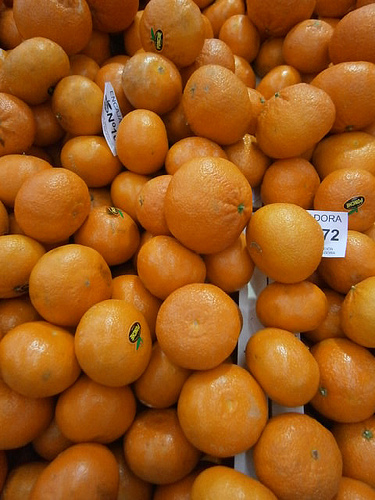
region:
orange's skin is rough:
[166, 165, 243, 248]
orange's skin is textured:
[174, 148, 212, 223]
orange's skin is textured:
[173, 168, 230, 232]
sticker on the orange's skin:
[124, 318, 149, 351]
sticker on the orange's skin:
[112, 316, 145, 345]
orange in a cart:
[140, 272, 250, 375]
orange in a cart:
[71, 281, 147, 387]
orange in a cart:
[35, 232, 105, 329]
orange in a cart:
[148, 150, 238, 277]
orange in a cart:
[243, 196, 321, 278]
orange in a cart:
[245, 271, 328, 333]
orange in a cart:
[237, 318, 333, 412]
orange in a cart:
[252, 389, 345, 497]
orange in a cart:
[36, 436, 142, 498]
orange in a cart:
[0, 219, 57, 307]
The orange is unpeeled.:
[133, 0, 208, 72]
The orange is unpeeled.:
[0, 319, 81, 407]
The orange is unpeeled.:
[65, 288, 157, 396]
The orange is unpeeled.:
[151, 278, 250, 372]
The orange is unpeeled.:
[171, 355, 277, 470]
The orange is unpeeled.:
[246, 404, 342, 498]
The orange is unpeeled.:
[238, 317, 330, 418]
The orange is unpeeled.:
[22, 235, 121, 336]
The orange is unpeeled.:
[7, 159, 97, 248]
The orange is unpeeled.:
[241, 191, 328, 297]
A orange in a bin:
[30, 440, 121, 498]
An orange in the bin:
[125, 409, 198, 482]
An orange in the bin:
[188, 461, 272, 498]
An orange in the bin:
[254, 407, 347, 498]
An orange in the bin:
[244, 327, 324, 406]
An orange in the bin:
[155, 277, 246, 368]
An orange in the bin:
[134, 234, 209, 293]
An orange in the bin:
[244, 197, 331, 283]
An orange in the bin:
[261, 82, 334, 155]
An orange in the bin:
[119, 47, 184, 111]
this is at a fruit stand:
[26, 43, 340, 398]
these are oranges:
[32, 256, 234, 492]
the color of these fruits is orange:
[33, 293, 156, 457]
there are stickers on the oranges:
[119, 311, 161, 351]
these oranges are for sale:
[73, 257, 260, 484]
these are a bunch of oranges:
[55, 274, 205, 448]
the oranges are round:
[29, 257, 210, 412]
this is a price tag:
[96, 86, 168, 198]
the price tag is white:
[73, 86, 146, 136]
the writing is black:
[320, 215, 346, 247]